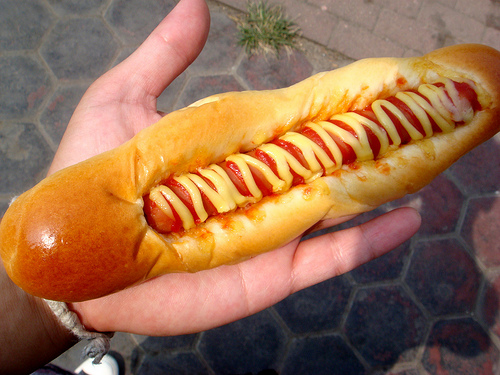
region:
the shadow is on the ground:
[328, 301, 490, 371]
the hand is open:
[98, 29, 414, 335]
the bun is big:
[32, 46, 490, 300]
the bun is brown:
[32, 172, 107, 277]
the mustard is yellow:
[204, 195, 234, 213]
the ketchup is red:
[222, 162, 242, 179]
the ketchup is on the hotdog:
[226, 160, 239, 180]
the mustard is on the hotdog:
[182, 170, 231, 210]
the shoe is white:
[77, 352, 118, 373]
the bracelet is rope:
[51, 318, 117, 363]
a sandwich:
[34, 49, 433, 302]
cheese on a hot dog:
[142, 160, 265, 235]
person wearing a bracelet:
[20, 285, 120, 345]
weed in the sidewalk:
[235, 0, 320, 55]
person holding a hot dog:
[96, 100, 416, 340]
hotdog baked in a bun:
[113, 67, 496, 204]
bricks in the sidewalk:
[314, 10, 424, 45]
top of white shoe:
[66, 352, 135, 374]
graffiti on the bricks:
[433, 192, 498, 320]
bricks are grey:
[29, 14, 83, 104]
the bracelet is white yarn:
[33, 291, 159, 371]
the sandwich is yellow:
[22, 86, 421, 346]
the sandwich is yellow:
[129, 134, 420, 263]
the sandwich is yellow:
[70, 12, 444, 241]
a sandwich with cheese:
[46, 85, 454, 366]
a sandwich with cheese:
[51, 46, 375, 262]